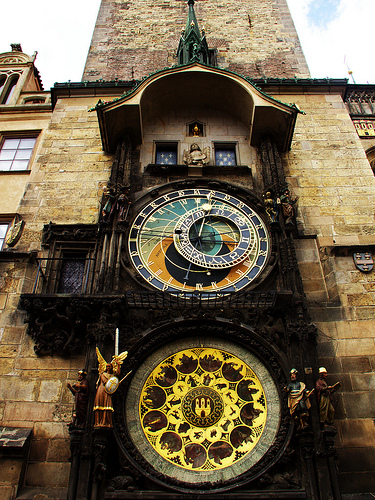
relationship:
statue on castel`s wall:
[282, 367, 311, 432] [0, 91, 375, 498]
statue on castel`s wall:
[314, 358, 344, 431] [0, 91, 375, 498]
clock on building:
[123, 183, 279, 303] [1, 2, 372, 499]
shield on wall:
[353, 250, 374, 271] [17, 99, 371, 495]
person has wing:
[95, 360, 118, 423] [110, 348, 128, 368]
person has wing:
[95, 360, 118, 423] [95, 346, 107, 373]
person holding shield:
[91, 346, 129, 429] [105, 375, 118, 395]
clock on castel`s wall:
[127, 188, 268, 302] [0, 91, 372, 498]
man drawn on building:
[183, 142, 211, 168] [1, 0, 374, 498]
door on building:
[0, 57, 28, 106] [1, 0, 374, 498]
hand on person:
[321, 377, 335, 394] [283, 367, 350, 425]